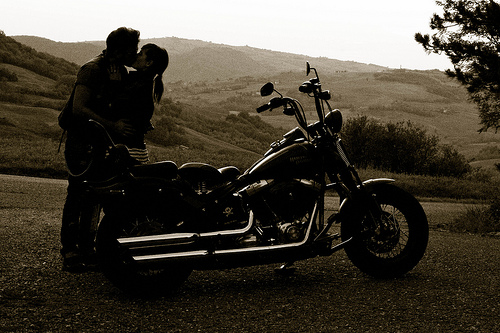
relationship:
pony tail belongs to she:
[149, 42, 175, 99] [93, 43, 168, 164]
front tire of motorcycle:
[338, 171, 442, 285] [132, 77, 432, 288]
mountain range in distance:
[11, 26, 385, 83] [197, 3, 395, 107]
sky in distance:
[228, 10, 374, 63] [197, 3, 395, 107]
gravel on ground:
[3, 174, 499, 327] [312, 290, 462, 327]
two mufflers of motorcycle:
[95, 202, 350, 264] [113, 94, 403, 240]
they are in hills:
[84, 17, 154, 151] [175, 69, 496, 196]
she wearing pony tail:
[132, 29, 166, 121] [149, 42, 175, 99]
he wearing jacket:
[77, 52, 127, 120] [115, 71, 161, 138]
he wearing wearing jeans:
[60, 26, 139, 273] [46, 128, 101, 274]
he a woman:
[60, 26, 139, 273] [131, 40, 173, 165]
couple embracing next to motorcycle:
[57, 26, 169, 273] [144, 126, 402, 255]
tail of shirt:
[117, 135, 155, 174] [116, 78, 160, 179]